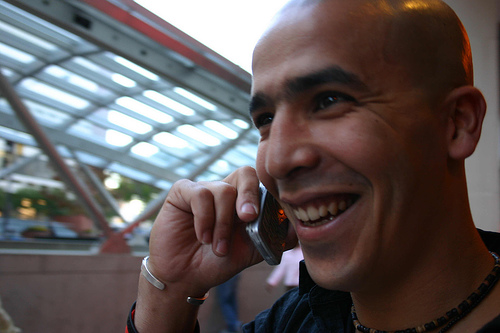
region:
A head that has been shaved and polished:
[246, 0, 488, 294]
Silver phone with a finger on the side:
[237, 160, 289, 266]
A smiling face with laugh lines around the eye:
[246, 26, 407, 288]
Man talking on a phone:
[123, 2, 498, 331]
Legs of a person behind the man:
[214, 275, 247, 332]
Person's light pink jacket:
[265, 249, 303, 287]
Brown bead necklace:
[333, 244, 498, 331]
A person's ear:
[445, 81, 486, 161]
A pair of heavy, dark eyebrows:
[246, 65, 368, 114]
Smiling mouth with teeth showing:
[274, 185, 369, 244]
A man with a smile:
[270, 185, 364, 241]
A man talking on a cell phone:
[215, 149, 287, 280]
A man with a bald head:
[247, 0, 497, 270]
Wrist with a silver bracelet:
[121, 216, 221, 316]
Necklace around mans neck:
[335, 270, 495, 327]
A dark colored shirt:
[262, 267, 327, 318]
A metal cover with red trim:
[6, 17, 151, 147]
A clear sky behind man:
[195, 5, 240, 50]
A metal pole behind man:
[55, 152, 131, 253]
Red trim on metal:
[132, 20, 239, 105]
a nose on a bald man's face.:
[256, 107, 317, 182]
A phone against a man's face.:
[241, 175, 306, 259]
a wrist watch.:
[130, 243, 217, 307]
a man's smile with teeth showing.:
[269, 177, 378, 250]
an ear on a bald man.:
[434, 83, 496, 173]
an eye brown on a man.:
[272, 51, 377, 102]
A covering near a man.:
[0, 0, 251, 330]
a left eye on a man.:
[261, 49, 387, 154]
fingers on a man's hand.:
[143, 177, 237, 283]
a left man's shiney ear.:
[421, 73, 496, 168]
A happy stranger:
[108, 6, 495, 331]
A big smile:
[277, 188, 377, 238]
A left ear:
[424, 81, 496, 157]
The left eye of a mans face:
[296, 85, 369, 115]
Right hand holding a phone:
[145, 160, 268, 275]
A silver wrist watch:
[125, 255, 220, 310]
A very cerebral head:
[213, 3, 491, 63]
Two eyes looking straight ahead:
[233, 70, 404, 132]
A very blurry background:
[0, 66, 218, 166]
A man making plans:
[136, 40, 491, 305]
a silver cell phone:
[247, 180, 287, 266]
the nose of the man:
[263, 102, 318, 177]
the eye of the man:
[316, 89, 352, 111]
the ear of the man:
[444, 84, 486, 159]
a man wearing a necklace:
[147, 1, 494, 328]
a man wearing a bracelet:
[121, 0, 498, 327]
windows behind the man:
[9, 4, 224, 179]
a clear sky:
[176, 3, 266, 25]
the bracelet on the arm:
[138, 255, 211, 302]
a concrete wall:
[1, 249, 127, 331]